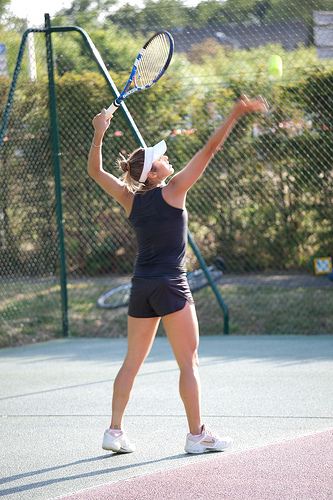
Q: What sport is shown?
A: Tennis.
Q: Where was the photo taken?
A: Tennis court.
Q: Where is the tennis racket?
A: Left hand.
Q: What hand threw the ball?
A: Right.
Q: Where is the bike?
A: On grass.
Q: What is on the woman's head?
A: Visor.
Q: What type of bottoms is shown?
A: Shorts.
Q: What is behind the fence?
A: Trees.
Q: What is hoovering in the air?
A: A tennis ball.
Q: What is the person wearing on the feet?
A: Shoes.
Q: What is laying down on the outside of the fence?
A: A bike.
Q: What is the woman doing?
A: Serving the ball.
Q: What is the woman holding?
A: A tennis racket.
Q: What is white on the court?
A: The woman's shoes.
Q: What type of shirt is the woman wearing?
A: A black tank top.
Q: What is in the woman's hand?
A: Tennis racket.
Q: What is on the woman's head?
A: A white visor.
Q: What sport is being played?
A: Tennis.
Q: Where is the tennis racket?
A: In the woman's hand.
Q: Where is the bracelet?
A: On the woman's wrist.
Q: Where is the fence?
A: Behind the woman.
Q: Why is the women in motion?
A: She is serving the ball.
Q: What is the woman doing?
A: Playing tennis.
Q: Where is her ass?
A: Under those shorts.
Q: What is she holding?
A: A tennis racket.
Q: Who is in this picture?
A: A woman.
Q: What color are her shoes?
A: White.